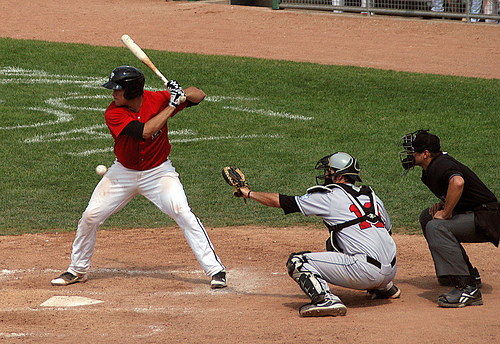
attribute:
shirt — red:
[94, 91, 175, 172]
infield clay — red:
[1, 225, 498, 342]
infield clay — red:
[2, 0, 497, 77]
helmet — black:
[102, 66, 146, 99]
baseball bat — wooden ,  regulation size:
[121, 35, 171, 92]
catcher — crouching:
[211, 128, 402, 322]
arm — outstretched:
[248, 188, 323, 213]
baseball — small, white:
[90, 160, 109, 186]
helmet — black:
[95, 52, 153, 105]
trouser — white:
[61, 152, 225, 274]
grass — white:
[215, 61, 427, 192]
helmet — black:
[99, 59, 179, 116]